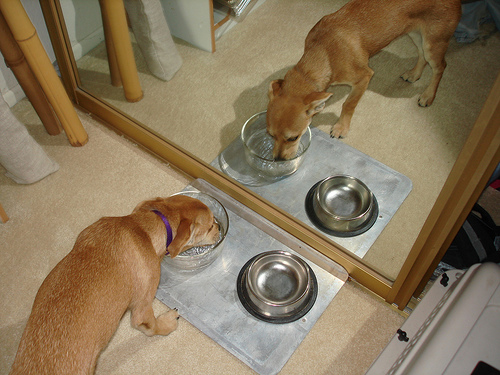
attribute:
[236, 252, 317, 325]
bowl — metal, rubber, silver, for food, stainless steel, empty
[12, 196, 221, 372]
dog — brown, eating, yellow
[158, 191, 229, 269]
bowl — glass, for water, clear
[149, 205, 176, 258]
collar — purple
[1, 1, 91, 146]
bamboo — a set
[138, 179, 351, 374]
matt — protective, rubber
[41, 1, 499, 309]
mirror — large, nice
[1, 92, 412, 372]
floor — tan, light in colore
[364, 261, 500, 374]
crate — for dog, white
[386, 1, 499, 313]
frame — brown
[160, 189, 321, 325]
dishes — for food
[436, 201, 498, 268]
travel bag — black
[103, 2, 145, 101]
pillar — wooden